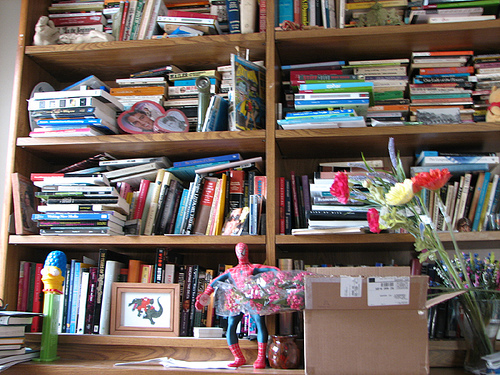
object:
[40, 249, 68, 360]
character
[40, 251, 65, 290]
head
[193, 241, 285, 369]
man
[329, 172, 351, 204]
flower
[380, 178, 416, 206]
flower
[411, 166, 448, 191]
flower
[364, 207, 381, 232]
flower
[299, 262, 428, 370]
box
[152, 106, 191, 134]
frame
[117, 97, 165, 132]
frame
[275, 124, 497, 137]
shelf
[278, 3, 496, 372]
case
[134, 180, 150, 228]
book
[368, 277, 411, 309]
sticker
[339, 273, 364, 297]
sticker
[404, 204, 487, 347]
stem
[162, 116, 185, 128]
image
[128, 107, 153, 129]
image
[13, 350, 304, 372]
shelf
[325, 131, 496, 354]
bouquet group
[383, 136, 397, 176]
flower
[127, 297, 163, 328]
image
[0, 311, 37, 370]
pile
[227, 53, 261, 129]
book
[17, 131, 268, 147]
shelf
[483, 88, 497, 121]
figurine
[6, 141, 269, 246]
shelf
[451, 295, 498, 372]
vase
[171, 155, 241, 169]
book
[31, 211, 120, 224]
book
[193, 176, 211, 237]
book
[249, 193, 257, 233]
book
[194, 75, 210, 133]
flashlight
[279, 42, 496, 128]
stacked books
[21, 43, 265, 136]
stacked books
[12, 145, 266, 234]
stacked books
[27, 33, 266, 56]
shelf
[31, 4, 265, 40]
stacked books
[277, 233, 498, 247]
shelf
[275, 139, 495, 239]
stacked books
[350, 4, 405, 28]
figurine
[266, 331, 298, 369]
vase